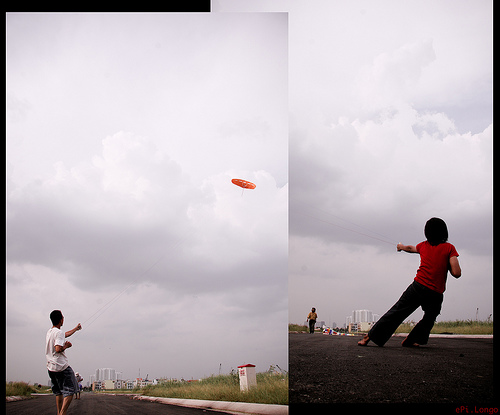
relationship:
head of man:
[46, 310, 67, 326] [44, 309, 84, 414]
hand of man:
[76, 323, 82, 329] [44, 309, 84, 414]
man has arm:
[44, 309, 84, 414] [64, 322, 86, 336]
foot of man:
[357, 335, 371, 347] [356, 213, 463, 352]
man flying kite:
[44, 309, 84, 414] [227, 176, 257, 194]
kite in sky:
[227, 176, 257, 194] [9, 3, 494, 312]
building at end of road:
[95, 361, 118, 386] [8, 377, 202, 414]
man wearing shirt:
[44, 309, 84, 414] [46, 327, 70, 374]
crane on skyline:
[217, 359, 224, 379] [142, 368, 287, 382]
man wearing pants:
[356, 213, 463, 352] [361, 273, 442, 346]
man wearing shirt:
[356, 213, 463, 352] [414, 241, 457, 292]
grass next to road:
[138, 375, 283, 405] [8, 377, 202, 414]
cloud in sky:
[33, 209, 241, 298] [9, 3, 494, 312]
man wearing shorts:
[44, 309, 84, 414] [49, 369, 80, 396]